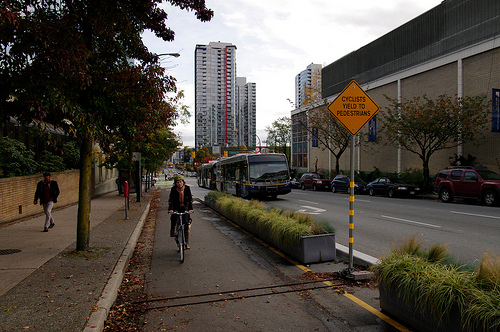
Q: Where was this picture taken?
A: A city.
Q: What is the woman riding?
A: A bicycle.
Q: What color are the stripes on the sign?
A: Yellow.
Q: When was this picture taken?
A: Daytime.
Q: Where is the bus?
A: On the street.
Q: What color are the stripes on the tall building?
A: Yellow and red.